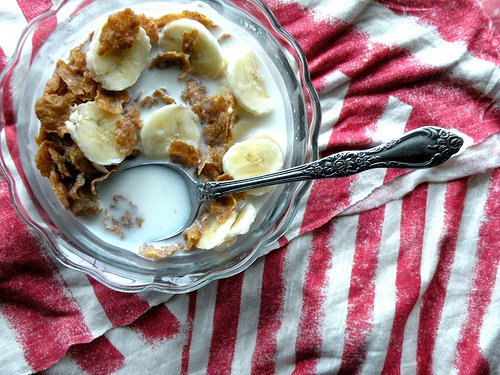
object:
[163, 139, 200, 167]
cereal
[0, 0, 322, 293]
bowl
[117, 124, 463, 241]
spoon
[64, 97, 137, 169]
bananas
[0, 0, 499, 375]
towel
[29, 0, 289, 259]
milk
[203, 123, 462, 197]
handle